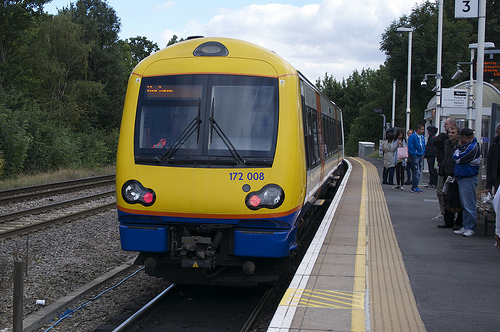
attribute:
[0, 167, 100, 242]
train tracks — light rail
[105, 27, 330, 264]
train — red, yellow, blue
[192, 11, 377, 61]
clouds — fluffly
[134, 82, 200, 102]
window — digital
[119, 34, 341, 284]
train — light rail, yellow, blue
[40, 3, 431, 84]
sky — bright blue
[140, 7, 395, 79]
sky — white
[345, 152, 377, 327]
stripe — yellow